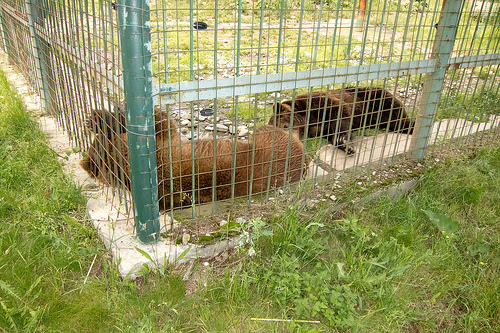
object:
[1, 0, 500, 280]
cage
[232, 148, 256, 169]
square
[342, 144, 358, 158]
paw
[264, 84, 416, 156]
bear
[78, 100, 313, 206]
dog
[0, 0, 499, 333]
weed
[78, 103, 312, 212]
bear